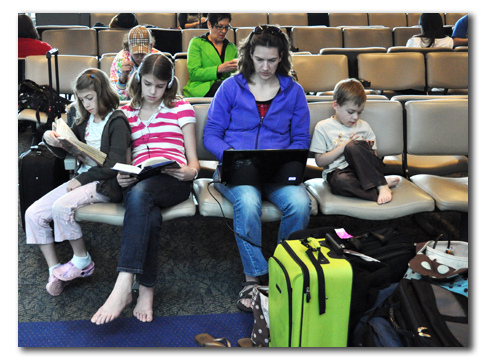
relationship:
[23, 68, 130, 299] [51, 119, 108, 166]
girl reading a book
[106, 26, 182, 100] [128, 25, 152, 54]
woman wearing a cap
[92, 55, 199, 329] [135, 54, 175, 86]
girl wearing headphones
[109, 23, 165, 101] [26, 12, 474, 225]
woman scattered throughout chairs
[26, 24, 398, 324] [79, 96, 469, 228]
group of people on row of front chairs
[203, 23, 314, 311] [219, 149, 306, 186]
woman working on laptop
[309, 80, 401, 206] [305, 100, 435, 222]
boy curled up on chair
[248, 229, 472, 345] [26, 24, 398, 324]
luggage piled in front of group of people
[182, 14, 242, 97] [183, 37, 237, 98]
woman in green jacket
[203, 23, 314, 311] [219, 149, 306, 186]
woman on a laptop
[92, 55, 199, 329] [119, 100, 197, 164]
girl in a striped shirt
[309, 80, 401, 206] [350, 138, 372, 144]
boy playing on a device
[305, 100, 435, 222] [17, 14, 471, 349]
chair at an airport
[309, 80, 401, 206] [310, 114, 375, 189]
boy wearing a tan shirt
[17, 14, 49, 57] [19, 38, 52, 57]
woman in red shirt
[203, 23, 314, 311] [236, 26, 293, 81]
woman with brown hair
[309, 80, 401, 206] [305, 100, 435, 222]
boy has feet on chair